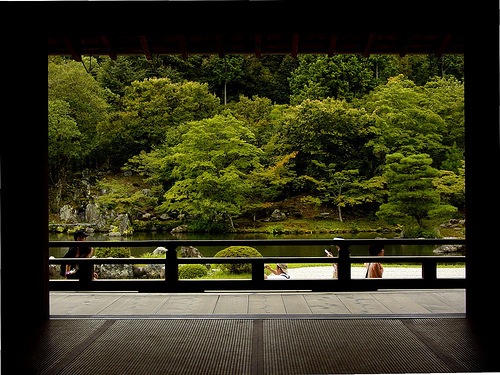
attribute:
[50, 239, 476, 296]
rail — black, short, wooden, dark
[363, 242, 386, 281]
woman — walking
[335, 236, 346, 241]
hat — tan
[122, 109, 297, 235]
tree — green, leafy, distant, large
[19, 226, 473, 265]
pond — calm, green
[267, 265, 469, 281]
sand — white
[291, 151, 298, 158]
leaf — yellow, green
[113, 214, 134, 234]
rock — gray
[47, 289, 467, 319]
walkway — wooden, gray, grooved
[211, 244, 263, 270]
bush — round, green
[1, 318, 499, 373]
carpet — striped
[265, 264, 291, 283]
person — sitting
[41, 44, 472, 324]
door — open